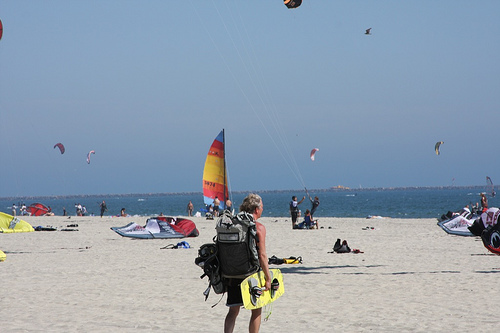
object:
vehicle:
[109, 216, 200, 239]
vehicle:
[436, 202, 500, 237]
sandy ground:
[0, 214, 500, 333]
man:
[223, 193, 272, 333]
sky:
[0, 0, 500, 197]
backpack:
[212, 209, 261, 279]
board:
[239, 267, 285, 310]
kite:
[434, 141, 444, 156]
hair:
[239, 193, 261, 215]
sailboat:
[199, 127, 233, 217]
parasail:
[309, 148, 319, 162]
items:
[353, 248, 365, 253]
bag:
[268, 254, 303, 265]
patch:
[219, 233, 240, 241]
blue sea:
[0, 185, 500, 219]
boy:
[309, 196, 321, 220]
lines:
[224, 0, 305, 188]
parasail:
[54, 142, 66, 154]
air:
[0, 0, 500, 197]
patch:
[30, 203, 38, 207]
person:
[304, 209, 319, 230]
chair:
[305, 216, 317, 230]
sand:
[0, 215, 500, 333]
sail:
[202, 130, 229, 210]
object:
[160, 241, 195, 250]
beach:
[0, 215, 500, 333]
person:
[289, 195, 306, 228]